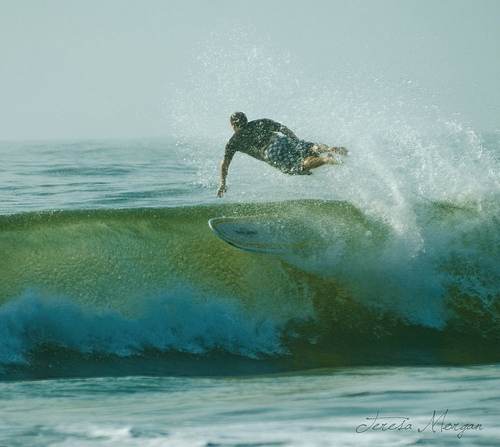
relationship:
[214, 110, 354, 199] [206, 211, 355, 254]
guy has board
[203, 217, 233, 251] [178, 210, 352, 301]
edge of bard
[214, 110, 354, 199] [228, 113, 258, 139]
guy has helmet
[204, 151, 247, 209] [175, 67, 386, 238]
arm of surfer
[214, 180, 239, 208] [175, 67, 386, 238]
hand of surfer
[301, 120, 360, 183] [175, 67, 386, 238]
leg of surfer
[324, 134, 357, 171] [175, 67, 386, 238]
foot of surfer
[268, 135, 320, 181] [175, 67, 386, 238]
short of surfer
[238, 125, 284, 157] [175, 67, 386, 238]
shirt of surfer